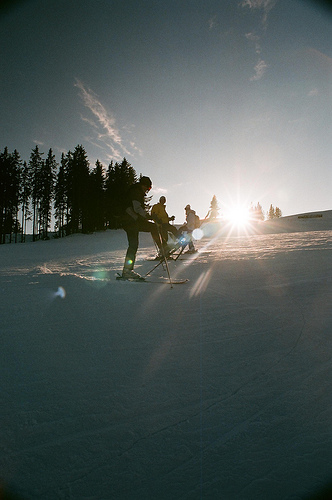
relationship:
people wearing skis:
[118, 173, 170, 280] [115, 273, 189, 283]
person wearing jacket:
[176, 205, 197, 254] [185, 211, 197, 232]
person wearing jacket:
[150, 196, 190, 258] [150, 203, 168, 228]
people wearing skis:
[117, 176, 203, 280] [115, 246, 214, 286]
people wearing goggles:
[118, 173, 170, 280] [141, 181, 153, 191]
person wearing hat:
[176, 205, 197, 254] [185, 205, 192, 210]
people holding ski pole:
[118, 173, 170, 280] [156, 220, 174, 291]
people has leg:
[118, 173, 170, 280] [139, 222, 170, 257]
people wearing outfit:
[118, 173, 170, 280] [119, 184, 168, 270]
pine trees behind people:
[0, 145, 153, 239] [118, 173, 170, 280]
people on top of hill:
[118, 173, 170, 280] [0, 210, 331, 498]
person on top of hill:
[176, 205, 197, 254] [0, 210, 331, 498]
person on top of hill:
[150, 196, 190, 258] [0, 210, 331, 498]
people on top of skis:
[118, 173, 170, 280] [115, 273, 189, 283]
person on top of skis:
[176, 205, 197, 254] [167, 250, 198, 255]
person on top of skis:
[150, 196, 190, 258] [150, 239, 190, 259]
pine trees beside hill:
[0, 145, 153, 239] [0, 210, 331, 498]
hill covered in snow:
[0, 210, 331, 498] [2, 211, 330, 499]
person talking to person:
[176, 205, 197, 254] [150, 196, 190, 258]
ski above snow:
[144, 238, 193, 277] [2, 211, 330, 499]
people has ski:
[118, 173, 170, 280] [144, 238, 193, 277]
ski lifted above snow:
[144, 238, 193, 277] [2, 211, 330, 499]